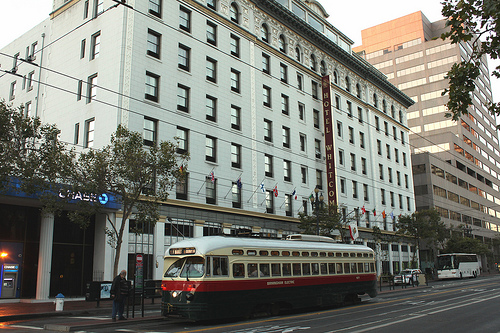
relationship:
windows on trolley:
[204, 246, 388, 288] [177, 232, 395, 320]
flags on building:
[138, 150, 407, 236] [21, 14, 419, 288]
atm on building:
[1, 256, 23, 296] [21, 14, 419, 288]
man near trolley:
[115, 263, 133, 315] [177, 232, 395, 320]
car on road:
[388, 259, 416, 291] [392, 286, 499, 326]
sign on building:
[321, 62, 341, 215] [21, 14, 419, 288]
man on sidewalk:
[115, 263, 133, 315] [5, 293, 156, 323]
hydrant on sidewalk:
[43, 287, 73, 313] [5, 293, 156, 323]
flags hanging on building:
[138, 150, 407, 236] [21, 14, 419, 288]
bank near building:
[1, 195, 140, 322] [21, 14, 419, 288]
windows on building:
[156, 6, 409, 214] [21, 14, 419, 288]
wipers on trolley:
[171, 263, 200, 287] [177, 232, 395, 320]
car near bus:
[392, 268, 422, 286] [441, 244, 481, 282]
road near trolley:
[392, 286, 499, 326] [177, 232, 395, 320]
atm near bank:
[1, 256, 23, 296] [1, 195, 140, 322]